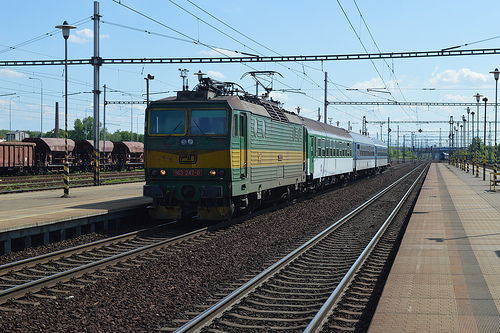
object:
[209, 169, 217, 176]
light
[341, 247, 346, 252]
pebble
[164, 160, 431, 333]
track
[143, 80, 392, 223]
train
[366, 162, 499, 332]
platform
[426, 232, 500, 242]
shadow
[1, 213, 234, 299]
track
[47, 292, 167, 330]
gravel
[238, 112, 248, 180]
door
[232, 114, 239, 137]
window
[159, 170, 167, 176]
headlight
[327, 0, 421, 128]
wire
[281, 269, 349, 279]
crosstie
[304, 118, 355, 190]
car